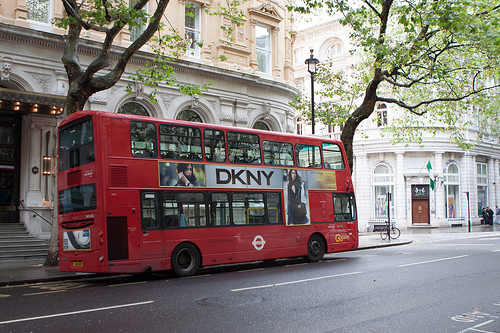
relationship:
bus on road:
[68, 102, 376, 271] [223, 259, 466, 307]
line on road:
[234, 267, 354, 288] [262, 260, 488, 309]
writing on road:
[450, 304, 499, 331] [321, 244, 496, 282]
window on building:
[234, 12, 278, 70] [144, 15, 360, 75]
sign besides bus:
[188, 150, 332, 207] [52, 105, 356, 253]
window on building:
[180, 3, 205, 54] [4, 3, 302, 251]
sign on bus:
[155, 157, 340, 227] [51, 108, 356, 276]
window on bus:
[142, 186, 283, 226] [51, 108, 356, 276]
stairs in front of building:
[0, 223, 50, 277] [6, 3, 299, 300]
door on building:
[4, 129, 25, 211] [6, 3, 299, 300]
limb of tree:
[79, 3, 145, 73] [58, 1, 173, 107]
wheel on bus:
[305, 237, 325, 263] [51, 108, 356, 276]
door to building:
[414, 184, 433, 226] [294, 10, 482, 232]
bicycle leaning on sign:
[380, 221, 399, 238] [385, 187, 393, 243]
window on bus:
[141, 190, 300, 230] [51, 108, 356, 276]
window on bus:
[333, 190, 356, 221] [51, 108, 356, 276]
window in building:
[378, 100, 389, 128] [294, 30, 484, 229]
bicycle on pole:
[380, 219, 402, 241] [384, 192, 394, 239]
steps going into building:
[4, 225, 53, 273] [4, 3, 302, 251]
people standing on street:
[482, 203, 483, 207] [364, 219, 479, 248]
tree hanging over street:
[307, 14, 478, 167] [42, 227, 484, 319]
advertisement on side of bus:
[150, 161, 339, 226] [51, 108, 356, 276]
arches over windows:
[114, 92, 278, 131] [125, 141, 282, 161]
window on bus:
[131, 127, 156, 156] [51, 108, 356, 276]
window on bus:
[224, 134, 262, 164] [51, 108, 356, 276]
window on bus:
[260, 142, 294, 165] [51, 108, 356, 276]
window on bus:
[332, 194, 356, 224] [51, 108, 356, 276]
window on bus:
[57, 182, 95, 213] [51, 108, 356, 276]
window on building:
[250, 17, 279, 75] [4, 3, 302, 251]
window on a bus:
[297, 145, 324, 166] [51, 108, 356, 276]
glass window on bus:
[141, 195, 159, 229] [58, 113, 358, 266]